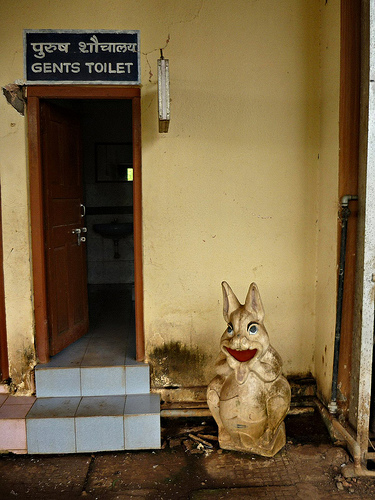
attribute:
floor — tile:
[217, 461, 309, 499]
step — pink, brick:
[1, 381, 40, 457]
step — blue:
[24, 393, 157, 453]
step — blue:
[34, 360, 147, 399]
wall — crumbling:
[0, 67, 32, 127]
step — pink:
[3, 395, 53, 451]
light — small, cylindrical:
[145, 41, 197, 140]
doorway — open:
[23, 88, 156, 368]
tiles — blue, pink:
[0, 363, 159, 459]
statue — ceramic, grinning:
[201, 273, 298, 469]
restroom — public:
[40, 88, 142, 368]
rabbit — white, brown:
[206, 280, 292, 457]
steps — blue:
[25, 353, 161, 453]